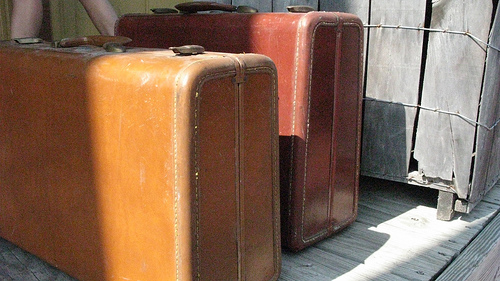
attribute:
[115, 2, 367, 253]
suit case — dark, brown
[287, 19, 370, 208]
suitcase — brown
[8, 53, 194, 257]
suitcase — brown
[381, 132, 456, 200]
ground — shaded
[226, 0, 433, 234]
luggage — rotten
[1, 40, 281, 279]
brown suitcase — old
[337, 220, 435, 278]
wood decking — faded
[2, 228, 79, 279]
floor — pale, grey, wood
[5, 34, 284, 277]
briefcase — orange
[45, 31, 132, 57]
handle — silver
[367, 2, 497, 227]
box — wooden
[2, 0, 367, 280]
suitcases — old, dusty, brown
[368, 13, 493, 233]
box — wooden 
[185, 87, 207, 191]
appointments — bronze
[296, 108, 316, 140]
appointments — bronze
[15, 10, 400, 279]
suitcases — tightly fitted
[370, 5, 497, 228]
crate — wood